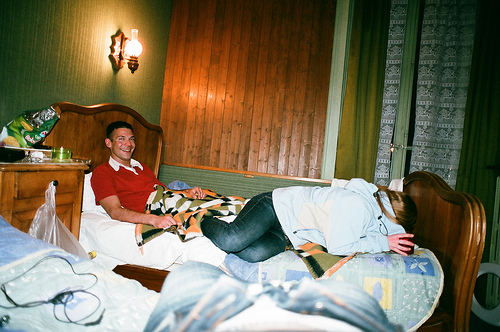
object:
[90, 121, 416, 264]
couple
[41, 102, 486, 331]
bed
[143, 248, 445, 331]
blanket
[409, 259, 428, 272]
butterfly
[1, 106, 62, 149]
bag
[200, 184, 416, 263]
woman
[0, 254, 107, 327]
cord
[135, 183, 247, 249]
quilt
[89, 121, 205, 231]
man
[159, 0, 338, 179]
blinds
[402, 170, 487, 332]
footboard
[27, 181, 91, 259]
bag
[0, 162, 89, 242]
nightstand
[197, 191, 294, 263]
jeans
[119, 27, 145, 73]
light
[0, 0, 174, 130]
wall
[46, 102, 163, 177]
headboard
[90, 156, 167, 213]
shirt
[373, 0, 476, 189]
drapes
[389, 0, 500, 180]
door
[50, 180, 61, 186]
knob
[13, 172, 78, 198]
drawer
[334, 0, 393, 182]
drape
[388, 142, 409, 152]
knob